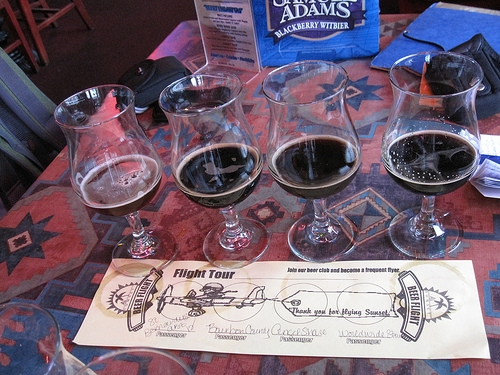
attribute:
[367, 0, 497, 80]
blue folder — black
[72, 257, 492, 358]
menu — flight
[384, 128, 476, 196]
liquid — light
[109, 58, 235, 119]
case — black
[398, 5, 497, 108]
case — black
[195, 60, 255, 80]
clear stand — plastic, with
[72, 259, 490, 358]
paper — white